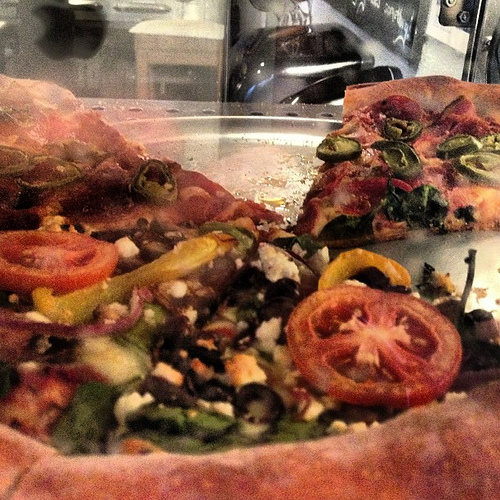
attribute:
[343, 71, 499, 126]
crust — brown, thin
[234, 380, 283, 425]
vegetable — black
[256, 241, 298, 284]
cheese — white, feta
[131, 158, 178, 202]
jalapeno — green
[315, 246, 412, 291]
vegetable — yellow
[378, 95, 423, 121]
pepperoni — red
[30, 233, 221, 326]
pepper — yellow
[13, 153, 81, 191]
pepper — green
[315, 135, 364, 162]
chili — hot, green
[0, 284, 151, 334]
onion — red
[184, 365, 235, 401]
olive — black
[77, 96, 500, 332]
plate — silver, shiny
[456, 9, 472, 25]
nut — hexagonal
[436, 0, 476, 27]
plate — black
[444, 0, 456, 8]
nut — hexagonal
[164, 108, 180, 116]
spot — round